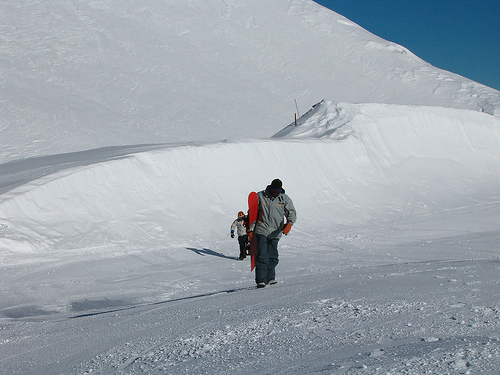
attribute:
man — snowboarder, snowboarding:
[249, 178, 296, 287]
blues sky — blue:
[320, 1, 498, 91]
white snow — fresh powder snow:
[1, 1, 231, 375]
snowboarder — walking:
[257, 179, 296, 287]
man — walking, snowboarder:
[230, 211, 247, 262]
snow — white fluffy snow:
[1, 2, 498, 178]